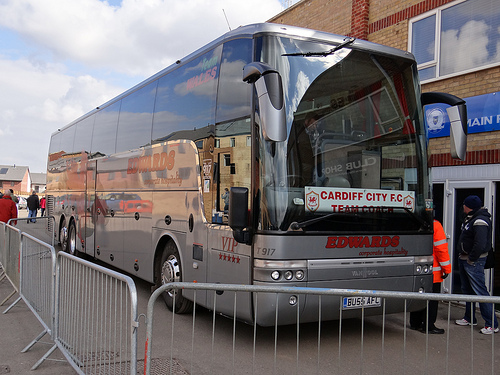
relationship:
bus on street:
[44, 22, 435, 332] [2, 200, 499, 373]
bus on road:
[44, 22, 435, 332] [8, 312, 498, 369]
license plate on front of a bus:
[344, 295, 379, 307] [44, 22, 435, 332]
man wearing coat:
[406, 214, 455, 334] [429, 220, 452, 284]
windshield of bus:
[253, 30, 433, 233] [44, 22, 435, 332]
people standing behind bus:
[3, 185, 59, 226] [12, 12, 459, 339]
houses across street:
[0, 166, 46, 206] [2, 200, 499, 373]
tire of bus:
[153, 237, 199, 314] [44, 22, 435, 332]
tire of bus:
[57, 212, 69, 251] [44, 22, 435, 332]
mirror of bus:
[255, 72, 289, 145] [44, 22, 435, 332]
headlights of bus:
[268, 267, 308, 282] [44, 22, 435, 332]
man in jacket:
[410, 218, 452, 335] [432, 218, 451, 281]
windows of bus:
[387, 0, 496, 88] [12, 12, 459, 339]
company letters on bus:
[323, 234, 401, 249] [44, 22, 435, 332]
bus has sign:
[44, 22, 435, 332] [301, 180, 423, 225]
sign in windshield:
[301, 180, 423, 225] [253, 30, 433, 233]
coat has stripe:
[429, 210, 451, 287] [430, 235, 451, 249]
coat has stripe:
[429, 210, 451, 287] [427, 256, 450, 275]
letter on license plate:
[348, 295, 356, 311] [363, 277, 388, 318]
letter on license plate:
[365, 294, 373, 306] [363, 277, 388, 318]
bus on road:
[74, 39, 491, 271] [8, 213, 481, 356]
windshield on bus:
[253, 30, 433, 233] [44, 22, 435, 332]